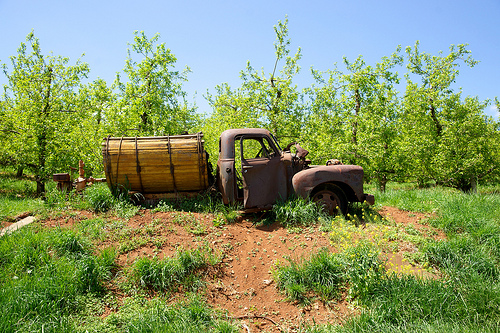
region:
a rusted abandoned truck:
[212, 120, 373, 221]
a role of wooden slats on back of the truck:
[97, 132, 208, 196]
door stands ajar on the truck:
[238, 128, 290, 213]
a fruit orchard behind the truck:
[0, 36, 492, 192]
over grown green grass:
[288, 180, 498, 330]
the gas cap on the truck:
[223, 162, 235, 177]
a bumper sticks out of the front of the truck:
[360, 179, 377, 214]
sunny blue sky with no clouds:
[0, 0, 499, 116]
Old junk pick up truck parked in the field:
[78, 115, 375, 222]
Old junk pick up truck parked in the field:
[218, 120, 380, 213]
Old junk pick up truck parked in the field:
[90, 82, 375, 207]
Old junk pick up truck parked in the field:
[88, 118, 386, 213]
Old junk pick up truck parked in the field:
[203, 113, 389, 220]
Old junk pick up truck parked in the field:
[82, 117, 379, 222]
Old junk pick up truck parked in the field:
[86, 121, 381, 216]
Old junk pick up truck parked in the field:
[83, 108, 378, 211]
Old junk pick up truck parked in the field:
[90, 114, 384, 216]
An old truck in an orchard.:
[101, 127, 374, 219]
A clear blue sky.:
[1, 1, 499, 128]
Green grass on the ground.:
[0, 167, 499, 332]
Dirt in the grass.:
[3, 204, 448, 331]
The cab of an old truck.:
[216, 128, 286, 216]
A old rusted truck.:
[216, 125, 374, 217]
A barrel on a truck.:
[100, 133, 214, 194]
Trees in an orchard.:
[2, 13, 497, 200]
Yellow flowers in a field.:
[317, 200, 442, 276]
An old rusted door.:
[238, 133, 277, 210]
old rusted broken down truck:
[208, 131, 373, 218]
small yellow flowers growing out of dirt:
[328, 203, 399, 265]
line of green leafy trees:
[3, 45, 494, 194]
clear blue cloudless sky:
[25, 5, 496, 60]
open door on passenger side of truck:
[237, 132, 286, 212]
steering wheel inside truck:
[251, 142, 264, 157]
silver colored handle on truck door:
[242, 160, 254, 175]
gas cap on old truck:
[223, 165, 231, 177]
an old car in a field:
[92, 120, 377, 245]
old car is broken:
[205, 115, 375, 227]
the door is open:
[226, 126, 283, 220]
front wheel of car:
[309, 178, 356, 230]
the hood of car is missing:
[270, 138, 360, 184]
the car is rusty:
[208, 125, 370, 218]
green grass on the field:
[6, 210, 207, 325]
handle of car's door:
[237, 161, 259, 171]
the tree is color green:
[381, 36, 493, 184]